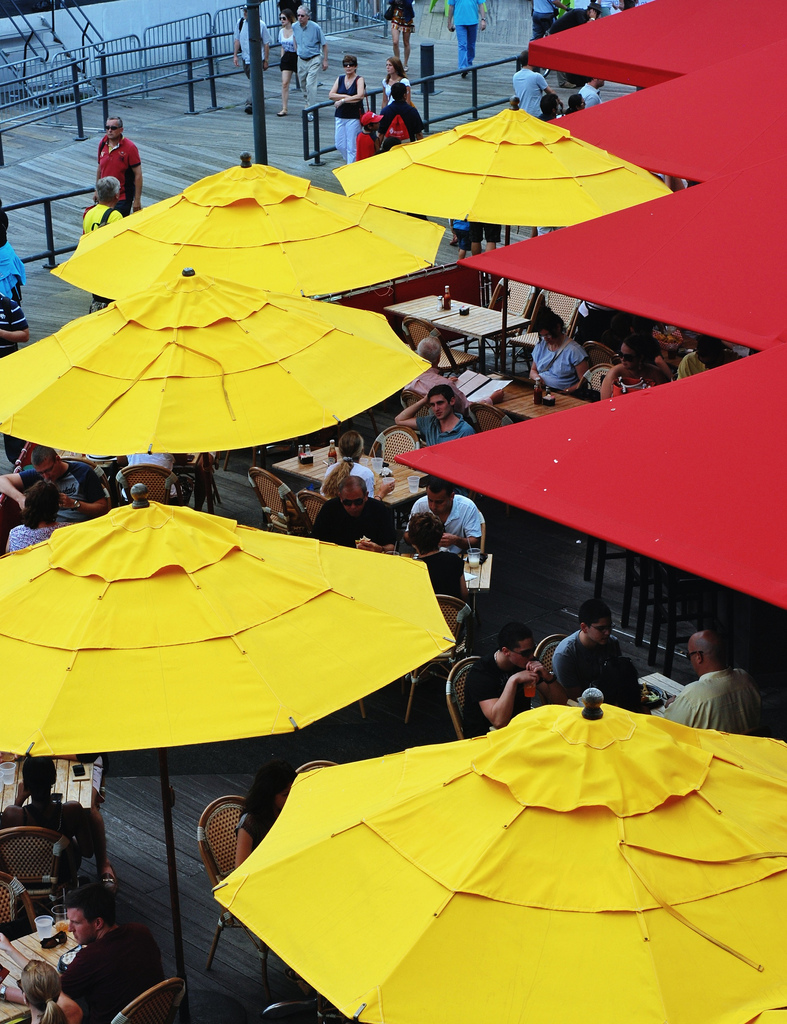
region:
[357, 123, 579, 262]
an umbrella that is yellow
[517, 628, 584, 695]
a chair that is brown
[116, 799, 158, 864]
floors that are hardwood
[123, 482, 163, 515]
the tip of a yellow umbrella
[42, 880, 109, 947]
the head of a man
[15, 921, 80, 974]
a brown wooden table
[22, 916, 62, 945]
a clear cup on a table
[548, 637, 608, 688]
a shirt that a man is wearing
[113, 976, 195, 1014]
chair at the table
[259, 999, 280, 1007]
chair at the table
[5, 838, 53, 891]
chair at the table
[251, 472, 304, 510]
chair at the table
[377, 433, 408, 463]
chair at the table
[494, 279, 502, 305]
chair at the table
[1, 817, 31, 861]
chair at the table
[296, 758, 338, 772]
chair at the table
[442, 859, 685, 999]
tent above the table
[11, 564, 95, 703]
tent above the table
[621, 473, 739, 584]
tent above the table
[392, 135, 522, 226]
tent above the table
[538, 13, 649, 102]
tent above the table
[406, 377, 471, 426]
the head of a man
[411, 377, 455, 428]
the hair of a man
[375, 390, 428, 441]
the elbow of a man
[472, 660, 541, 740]
the arm of a man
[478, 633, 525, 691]
the neck of a man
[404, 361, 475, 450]
a man wearing a blue shirt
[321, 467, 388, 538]
the face of a man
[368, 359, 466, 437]
the arm of a man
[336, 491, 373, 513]
man wearing pair of sunglasses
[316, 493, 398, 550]
man wearing a shirt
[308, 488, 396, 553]
man's shirt is black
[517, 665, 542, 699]
man holding cup of drink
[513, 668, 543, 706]
man's drink is orange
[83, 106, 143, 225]
man walking on pier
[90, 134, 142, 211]
man wearing red shirt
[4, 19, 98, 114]
steps leading upwards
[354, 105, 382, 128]
man wearing a cap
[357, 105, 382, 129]
man's cap is red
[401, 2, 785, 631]
red square roof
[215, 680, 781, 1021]
wide open yellow umbrella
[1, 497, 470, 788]
wide open yellow umbrella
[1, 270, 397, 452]
wide open yellow umbrella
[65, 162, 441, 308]
wide open yellow umbrella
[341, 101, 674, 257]
wide open yellow umbrella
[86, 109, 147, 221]
man wearing red shirt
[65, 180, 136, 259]
man wearing yellow shirt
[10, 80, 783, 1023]
bright yellow layered umbrellas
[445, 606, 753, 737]
three men sit at a table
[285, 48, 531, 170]
black metal railing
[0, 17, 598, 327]
wooden walkway passes an outdoor cafe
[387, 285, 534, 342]
rectangular table with ketchup on it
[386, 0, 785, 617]
square corners on red awnings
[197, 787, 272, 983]
ratten chair with caned back and seat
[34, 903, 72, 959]
plastic water cup with sunglasses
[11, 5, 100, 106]
stairway with black metal railings